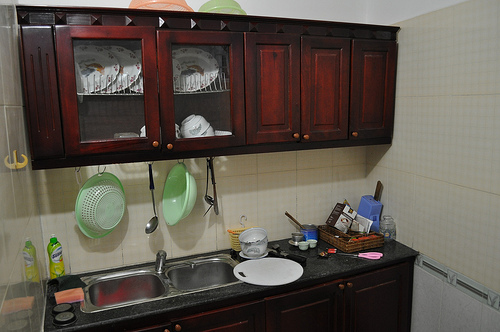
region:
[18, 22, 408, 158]
reddish black wood of cabinets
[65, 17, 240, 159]
windows showing dishes and cups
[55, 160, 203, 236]
ladle hanging between green colanders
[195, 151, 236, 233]
utensils hanging together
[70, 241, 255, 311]
double sinks in metal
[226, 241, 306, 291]
plate hanging off counter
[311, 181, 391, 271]
tray filled with items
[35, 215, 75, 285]
bottle sitting in corner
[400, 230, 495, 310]
border tile at counter height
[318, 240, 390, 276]
pink scissors on counter top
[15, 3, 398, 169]
the overhead kitchen cabinets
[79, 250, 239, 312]
dual stainless steel kitchen sinks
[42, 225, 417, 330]
a burgandy wooden kitchen counter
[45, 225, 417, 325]
a black kitchen counter top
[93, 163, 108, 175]
a hook for hanging kitchen utensils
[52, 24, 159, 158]
a glass kitchen cabinet door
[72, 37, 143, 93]
dinner plates stored in the overhead kitchen cabinet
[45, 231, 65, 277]
a bottle of suave dish soap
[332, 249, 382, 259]
a pair of scissors with pink handles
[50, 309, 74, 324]
a black drain sink stopper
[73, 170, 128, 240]
green strainer handing under cupbaord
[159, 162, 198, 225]
green bowl hanging under cupboard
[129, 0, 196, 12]
pink bowl above cupboard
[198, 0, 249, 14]
green bowl above cupboard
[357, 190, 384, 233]
blue knife block in corner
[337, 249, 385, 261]
pink handled scissors on counter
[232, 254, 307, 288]
white plate near sink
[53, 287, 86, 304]
pink sponge to left of sink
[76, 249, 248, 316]
silver double sink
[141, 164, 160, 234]
spoon handing near strainer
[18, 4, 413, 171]
dark brown wooden cabinet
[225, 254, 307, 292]
white plate sitting on a cabinet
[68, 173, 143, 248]
green drainer hanging up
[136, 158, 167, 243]
ladle hanging up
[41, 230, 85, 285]
dish liquid sitting on side of sink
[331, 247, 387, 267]
pair of scissors with pink handle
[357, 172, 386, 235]
light blue cutting block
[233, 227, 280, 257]
white bowl with saucer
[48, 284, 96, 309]
pink sponge on side on sink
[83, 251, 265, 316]
stainless steel sink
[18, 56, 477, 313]
a very small kitchen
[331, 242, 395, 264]
some pink handled scissors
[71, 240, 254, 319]
a two compartment sink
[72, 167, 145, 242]
a pale green colander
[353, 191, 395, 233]
plastic blue knife block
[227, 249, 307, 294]
a round white cutting board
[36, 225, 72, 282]
a bottle of dish soap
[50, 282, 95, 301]
an orange sponge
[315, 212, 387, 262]
a brown wicker basket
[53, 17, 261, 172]
cabinets with glass doors